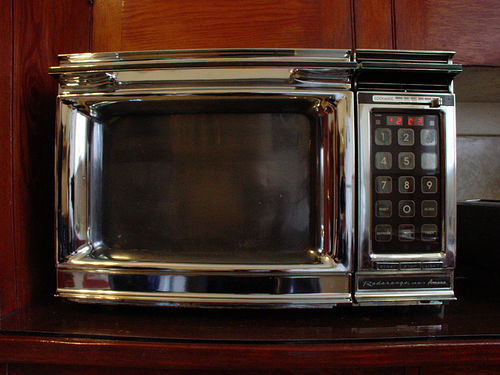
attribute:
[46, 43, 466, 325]
microwave — silver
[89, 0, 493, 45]
cabinets — wood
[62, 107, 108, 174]
reflection — light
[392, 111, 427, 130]
numbers — red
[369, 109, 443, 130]
display — digital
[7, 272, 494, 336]
glass — flat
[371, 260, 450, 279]
buttons — three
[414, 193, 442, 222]
button — square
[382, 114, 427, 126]
timer — digital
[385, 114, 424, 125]
letters — red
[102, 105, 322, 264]
door — see through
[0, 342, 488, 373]
shelf — brown